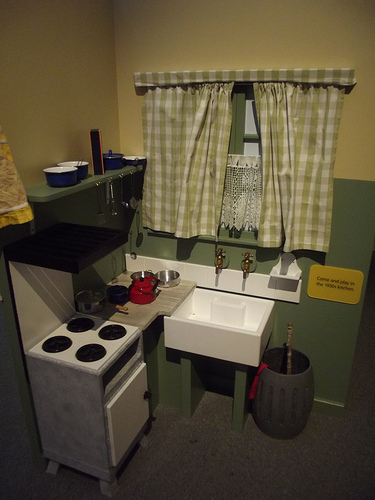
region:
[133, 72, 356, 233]
curtain on top of window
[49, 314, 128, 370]
black stove top on counter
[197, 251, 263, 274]
silver sink facuet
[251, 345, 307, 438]
small trash can in corner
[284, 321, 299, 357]
faucet piece in can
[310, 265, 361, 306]
yellow sign on the wall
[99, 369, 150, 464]
cabinet below the stove tp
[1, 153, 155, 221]
shelf above stove top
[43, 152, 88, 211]
bowls on the shelf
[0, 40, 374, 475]
miniature kitchen set up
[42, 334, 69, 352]
black metal burner on stove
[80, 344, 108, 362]
black metal burner on stove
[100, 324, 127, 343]
black metal burner on stove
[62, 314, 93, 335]
black metal burner on stove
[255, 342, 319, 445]
plastic barrel on right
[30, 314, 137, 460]
white stove on left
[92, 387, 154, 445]
white door on gray stove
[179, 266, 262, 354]
white sink against wall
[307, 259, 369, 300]
yellow sign on wall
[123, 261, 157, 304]
red pot on table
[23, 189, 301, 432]
toy kitchen with a stove, sink and countertop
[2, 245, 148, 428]
toy stove for children to play with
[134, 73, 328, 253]
window in a toy kitchen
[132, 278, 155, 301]
red toy tea pot for children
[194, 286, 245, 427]
toy sink in a toy kitchen for children to play with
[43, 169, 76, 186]
toy bowl that is blue.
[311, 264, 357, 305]
yellow sign that invites people to play in the toy kitchen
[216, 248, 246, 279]
brass toy faucets for a toy kitchen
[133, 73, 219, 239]
yellow and white check curtains covering a window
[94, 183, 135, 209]
toy utensils for children to use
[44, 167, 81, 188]
blue pot on shelf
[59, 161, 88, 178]
blue pot on shelf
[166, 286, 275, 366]
white sink in front of window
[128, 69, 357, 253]
green curtain covering window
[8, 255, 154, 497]
white stove next to counter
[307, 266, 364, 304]
yellow sign next to sink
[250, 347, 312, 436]
gray bucket next to sink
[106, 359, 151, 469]
white oven door with black knob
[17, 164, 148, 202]
green shelve with pots on top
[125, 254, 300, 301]
white backsplash above sink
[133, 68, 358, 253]
Green-and-white curtains in replica of kitchen.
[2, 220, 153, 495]
Old cooking stove in replica of kitchen.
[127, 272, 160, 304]
Red teapot in replica of kitchen.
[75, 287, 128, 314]
Sauce pan with lid in replica of kitchen.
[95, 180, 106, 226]
Spatula in replica of kitchen.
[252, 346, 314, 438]
Barrel in replica of kitchen.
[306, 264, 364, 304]
Sign identifying replica of old-time kitchen.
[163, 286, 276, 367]
White sink in replica of kitchen.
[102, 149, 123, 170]
Blue pot with lid.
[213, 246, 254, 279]
Brass faucet handles in replica of kitchen.